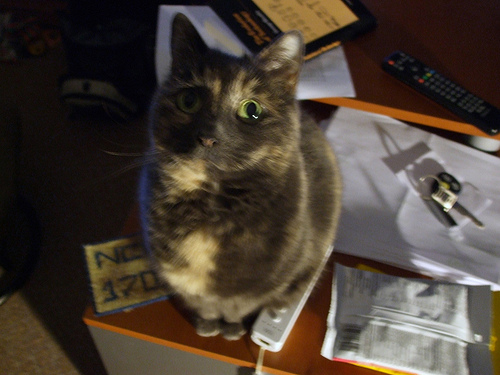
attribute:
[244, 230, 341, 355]
whii remote — Wii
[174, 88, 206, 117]
eye — green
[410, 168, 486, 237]
keys — black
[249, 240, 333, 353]
controller — video game, white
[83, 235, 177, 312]
sign — brown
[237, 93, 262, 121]
eye — green, black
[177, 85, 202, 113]
eye — black, green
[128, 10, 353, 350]
cat — calico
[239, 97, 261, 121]
eye — green